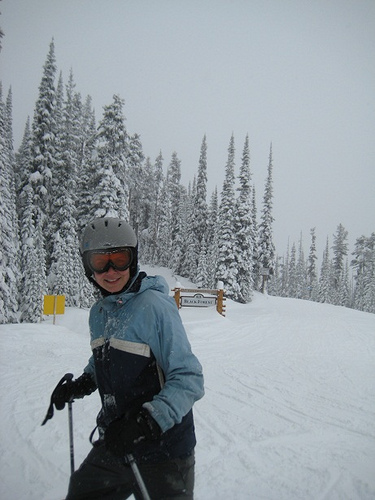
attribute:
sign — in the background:
[173, 286, 226, 318]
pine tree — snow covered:
[257, 144, 278, 294]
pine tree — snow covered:
[213, 132, 254, 299]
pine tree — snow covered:
[304, 225, 317, 298]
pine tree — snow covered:
[196, 135, 207, 253]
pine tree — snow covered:
[0, 92, 25, 320]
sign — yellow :
[40, 295, 65, 322]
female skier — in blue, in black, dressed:
[40, 214, 207, 497]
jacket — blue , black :
[64, 272, 209, 432]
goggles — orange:
[83, 249, 132, 271]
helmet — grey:
[80, 215, 136, 247]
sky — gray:
[2, 0, 370, 182]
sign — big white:
[171, 287, 225, 314]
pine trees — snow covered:
[0, 39, 365, 299]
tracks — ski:
[234, 363, 331, 429]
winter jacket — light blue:
[70, 266, 205, 459]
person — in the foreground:
[40, 215, 206, 498]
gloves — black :
[50, 375, 157, 458]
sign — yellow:
[31, 283, 85, 337]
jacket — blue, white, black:
[74, 267, 203, 432]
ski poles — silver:
[56, 366, 152, 498]